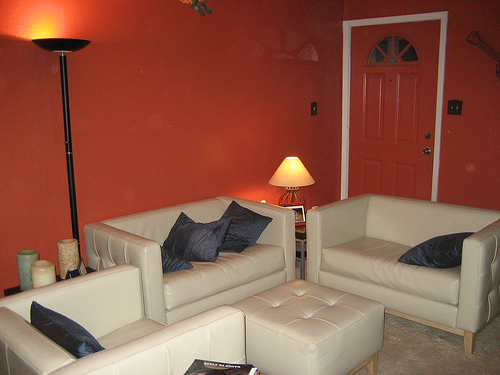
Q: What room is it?
A: It is a living room.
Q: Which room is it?
A: It is a living room.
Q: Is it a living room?
A: Yes, it is a living room.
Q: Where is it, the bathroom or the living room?
A: It is the living room.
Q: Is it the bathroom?
A: No, it is the living room.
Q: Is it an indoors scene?
A: Yes, it is indoors.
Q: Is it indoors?
A: Yes, it is indoors.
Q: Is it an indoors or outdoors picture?
A: It is indoors.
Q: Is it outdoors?
A: No, it is indoors.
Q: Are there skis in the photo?
A: No, there are no skis.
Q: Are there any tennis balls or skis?
A: No, there are no skis or tennis balls.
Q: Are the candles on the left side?
A: Yes, the candles are on the left of the image.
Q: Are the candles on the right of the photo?
A: No, the candles are on the left of the image.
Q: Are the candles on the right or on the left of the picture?
A: The candles are on the left of the image.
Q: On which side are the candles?
A: The candles are on the left of the image.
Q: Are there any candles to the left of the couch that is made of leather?
A: Yes, there are candles to the left of the couch.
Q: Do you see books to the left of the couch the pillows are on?
A: No, there are candles to the left of the couch.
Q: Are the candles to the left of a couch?
A: Yes, the candles are to the left of a couch.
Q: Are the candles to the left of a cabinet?
A: No, the candles are to the left of a couch.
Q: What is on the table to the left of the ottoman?
A: The candles are on the table.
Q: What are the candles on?
A: The candles are on the table.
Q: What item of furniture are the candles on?
A: The candles are on the table.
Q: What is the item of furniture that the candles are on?
A: The piece of furniture is a table.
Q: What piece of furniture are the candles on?
A: The candles are on the table.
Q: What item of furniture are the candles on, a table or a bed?
A: The candles are on a table.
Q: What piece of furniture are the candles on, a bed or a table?
A: The candles are on a table.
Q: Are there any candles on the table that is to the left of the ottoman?
A: Yes, there are candles on the table.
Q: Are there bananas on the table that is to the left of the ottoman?
A: No, there are candles on the table.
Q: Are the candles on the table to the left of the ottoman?
A: Yes, the candles are on the table.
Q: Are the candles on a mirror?
A: No, the candles are on the table.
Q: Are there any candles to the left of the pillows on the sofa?
A: Yes, there are candles to the left of the pillows.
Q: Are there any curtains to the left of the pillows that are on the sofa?
A: No, there are candles to the left of the pillows.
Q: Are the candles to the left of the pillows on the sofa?
A: Yes, the candles are to the left of the pillows.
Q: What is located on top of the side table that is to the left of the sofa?
A: The candles are on top of the side table.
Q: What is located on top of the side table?
A: The candles are on top of the side table.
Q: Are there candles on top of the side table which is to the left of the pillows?
A: Yes, there are candles on top of the side table.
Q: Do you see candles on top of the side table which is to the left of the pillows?
A: Yes, there are candles on top of the side table.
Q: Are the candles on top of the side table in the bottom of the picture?
A: Yes, the candles are on top of the side table.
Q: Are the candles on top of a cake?
A: No, the candles are on top of the side table.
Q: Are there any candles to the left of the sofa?
A: Yes, there are candles to the left of the sofa.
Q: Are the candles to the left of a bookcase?
A: No, the candles are to the left of the sofa.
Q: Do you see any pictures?
A: No, there are no pictures.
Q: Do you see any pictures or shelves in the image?
A: No, there are no pictures or shelves.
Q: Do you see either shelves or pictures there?
A: No, there are no pictures or shelves.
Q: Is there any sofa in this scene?
A: Yes, there is a sofa.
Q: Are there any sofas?
A: Yes, there is a sofa.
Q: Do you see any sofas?
A: Yes, there is a sofa.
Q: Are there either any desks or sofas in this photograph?
A: Yes, there is a sofa.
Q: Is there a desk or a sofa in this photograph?
A: Yes, there is a sofa.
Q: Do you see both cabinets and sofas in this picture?
A: No, there is a sofa but no cabinets.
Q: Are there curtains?
A: No, there are no curtains.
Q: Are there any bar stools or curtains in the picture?
A: No, there are no curtains or bar stools.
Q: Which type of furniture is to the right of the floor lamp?
A: The piece of furniture is a sofa.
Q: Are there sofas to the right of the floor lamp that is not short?
A: Yes, there is a sofa to the right of the floor lamp.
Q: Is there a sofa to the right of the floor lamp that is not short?
A: Yes, there is a sofa to the right of the floor lamp.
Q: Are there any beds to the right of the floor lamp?
A: No, there is a sofa to the right of the floor lamp.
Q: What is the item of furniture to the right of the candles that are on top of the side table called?
A: The piece of furniture is a sofa.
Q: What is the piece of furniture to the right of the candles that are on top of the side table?
A: The piece of furniture is a sofa.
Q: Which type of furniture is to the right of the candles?
A: The piece of furniture is a sofa.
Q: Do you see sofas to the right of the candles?
A: Yes, there is a sofa to the right of the candles.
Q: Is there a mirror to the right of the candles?
A: No, there is a sofa to the right of the candles.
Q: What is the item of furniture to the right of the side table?
A: The piece of furniture is a sofa.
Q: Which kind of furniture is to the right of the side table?
A: The piece of furniture is a sofa.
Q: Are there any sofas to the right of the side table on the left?
A: Yes, there is a sofa to the right of the side table.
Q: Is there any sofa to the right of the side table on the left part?
A: Yes, there is a sofa to the right of the side table.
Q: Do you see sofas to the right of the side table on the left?
A: Yes, there is a sofa to the right of the side table.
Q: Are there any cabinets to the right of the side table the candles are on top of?
A: No, there is a sofa to the right of the side table.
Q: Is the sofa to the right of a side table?
A: Yes, the sofa is to the right of a side table.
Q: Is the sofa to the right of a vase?
A: No, the sofa is to the right of a side table.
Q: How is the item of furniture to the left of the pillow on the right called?
A: The piece of furniture is a sofa.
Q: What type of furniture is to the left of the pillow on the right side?
A: The piece of furniture is a sofa.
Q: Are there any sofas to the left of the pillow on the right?
A: Yes, there is a sofa to the left of the pillow.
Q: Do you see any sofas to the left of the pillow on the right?
A: Yes, there is a sofa to the left of the pillow.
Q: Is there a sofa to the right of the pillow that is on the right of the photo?
A: No, the sofa is to the left of the pillow.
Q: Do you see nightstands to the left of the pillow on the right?
A: No, there is a sofa to the left of the pillow.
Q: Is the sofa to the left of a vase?
A: No, the sofa is to the left of the pillow.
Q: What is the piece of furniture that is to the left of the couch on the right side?
A: The piece of furniture is a sofa.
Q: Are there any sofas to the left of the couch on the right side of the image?
A: Yes, there is a sofa to the left of the couch.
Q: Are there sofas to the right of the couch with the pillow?
A: No, the sofa is to the left of the couch.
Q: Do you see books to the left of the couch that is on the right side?
A: No, there is a sofa to the left of the couch.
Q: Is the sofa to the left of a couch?
A: Yes, the sofa is to the left of a couch.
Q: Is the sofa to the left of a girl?
A: No, the sofa is to the left of a couch.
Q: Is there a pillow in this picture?
A: Yes, there are pillows.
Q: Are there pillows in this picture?
A: Yes, there are pillows.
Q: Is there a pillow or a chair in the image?
A: Yes, there are pillows.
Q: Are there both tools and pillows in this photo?
A: No, there are pillows but no tools.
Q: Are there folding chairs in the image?
A: No, there are no folding chairs.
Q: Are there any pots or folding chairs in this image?
A: No, there are no folding chairs or pots.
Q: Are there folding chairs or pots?
A: No, there are no folding chairs or pots.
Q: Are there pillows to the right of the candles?
A: Yes, there are pillows to the right of the candles.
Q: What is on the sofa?
A: The pillows are on the sofa.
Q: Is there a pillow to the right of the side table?
A: Yes, there are pillows to the right of the side table.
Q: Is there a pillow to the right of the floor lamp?
A: Yes, there are pillows to the right of the floor lamp.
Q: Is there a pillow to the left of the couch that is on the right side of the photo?
A: Yes, there are pillows to the left of the couch.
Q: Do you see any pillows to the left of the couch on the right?
A: Yes, there are pillows to the left of the couch.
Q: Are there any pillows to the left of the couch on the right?
A: Yes, there are pillows to the left of the couch.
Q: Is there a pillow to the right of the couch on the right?
A: No, the pillows are to the left of the couch.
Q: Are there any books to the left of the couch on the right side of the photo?
A: No, there are pillows to the left of the couch.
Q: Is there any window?
A: Yes, there is a window.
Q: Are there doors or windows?
A: Yes, there is a window.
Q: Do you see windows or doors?
A: Yes, there is a window.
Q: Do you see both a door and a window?
A: Yes, there are both a window and a door.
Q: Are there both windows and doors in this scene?
A: Yes, there are both a window and doors.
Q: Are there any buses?
A: No, there are no buses.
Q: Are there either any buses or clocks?
A: No, there are no buses or clocks.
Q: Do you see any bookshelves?
A: No, there are no bookshelves.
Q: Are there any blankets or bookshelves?
A: No, there are no bookshelves or blankets.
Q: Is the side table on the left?
A: Yes, the side table is on the left of the image.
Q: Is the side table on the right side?
A: No, the side table is on the left of the image.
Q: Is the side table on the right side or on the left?
A: The side table is on the left of the image.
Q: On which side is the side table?
A: The side table is on the left of the image.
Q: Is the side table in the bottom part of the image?
A: Yes, the side table is in the bottom of the image.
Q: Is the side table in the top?
A: No, the side table is in the bottom of the image.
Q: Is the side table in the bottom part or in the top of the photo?
A: The side table is in the bottom of the image.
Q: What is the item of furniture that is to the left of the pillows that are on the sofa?
A: The piece of furniture is a side table.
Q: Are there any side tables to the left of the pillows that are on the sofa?
A: Yes, there is a side table to the left of the pillows.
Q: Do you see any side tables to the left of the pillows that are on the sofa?
A: Yes, there is a side table to the left of the pillows.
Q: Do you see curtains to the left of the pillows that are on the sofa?
A: No, there is a side table to the left of the pillows.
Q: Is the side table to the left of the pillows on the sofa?
A: Yes, the side table is to the left of the pillows.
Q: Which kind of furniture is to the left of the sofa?
A: The piece of furniture is a side table.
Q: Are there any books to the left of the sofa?
A: No, there is a side table to the left of the sofa.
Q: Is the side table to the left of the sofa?
A: Yes, the side table is to the left of the sofa.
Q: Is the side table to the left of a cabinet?
A: No, the side table is to the left of the sofa.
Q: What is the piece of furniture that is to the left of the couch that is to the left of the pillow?
A: The piece of furniture is a side table.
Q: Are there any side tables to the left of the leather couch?
A: Yes, there is a side table to the left of the couch.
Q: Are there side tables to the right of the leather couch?
A: No, the side table is to the left of the couch.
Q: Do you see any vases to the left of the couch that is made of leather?
A: No, there is a side table to the left of the couch.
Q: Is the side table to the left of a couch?
A: Yes, the side table is to the left of a couch.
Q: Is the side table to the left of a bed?
A: No, the side table is to the left of a couch.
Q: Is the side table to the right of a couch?
A: No, the side table is to the left of a couch.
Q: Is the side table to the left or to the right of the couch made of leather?
A: The side table is to the left of the couch.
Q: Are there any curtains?
A: No, there are no curtains.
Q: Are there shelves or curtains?
A: No, there are no curtains or shelves.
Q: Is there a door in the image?
A: Yes, there is a door.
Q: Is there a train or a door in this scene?
A: Yes, there is a door.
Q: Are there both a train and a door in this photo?
A: No, there is a door but no trains.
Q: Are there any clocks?
A: No, there are no clocks.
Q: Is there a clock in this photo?
A: No, there are no clocks.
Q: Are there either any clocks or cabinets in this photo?
A: No, there are no clocks or cabinets.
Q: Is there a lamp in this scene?
A: Yes, there is a lamp.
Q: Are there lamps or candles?
A: Yes, there is a lamp.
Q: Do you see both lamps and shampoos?
A: No, there is a lamp but no shampoos.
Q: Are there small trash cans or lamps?
A: Yes, there is a small lamp.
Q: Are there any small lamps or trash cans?
A: Yes, there is a small lamp.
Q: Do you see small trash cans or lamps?
A: Yes, there is a small lamp.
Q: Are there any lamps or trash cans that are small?
A: Yes, the lamp is small.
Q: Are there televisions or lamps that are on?
A: Yes, the lamp is on.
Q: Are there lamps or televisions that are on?
A: Yes, the lamp is on.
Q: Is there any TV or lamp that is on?
A: Yes, the lamp is on.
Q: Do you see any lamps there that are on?
A: Yes, there is a lamp that is on.